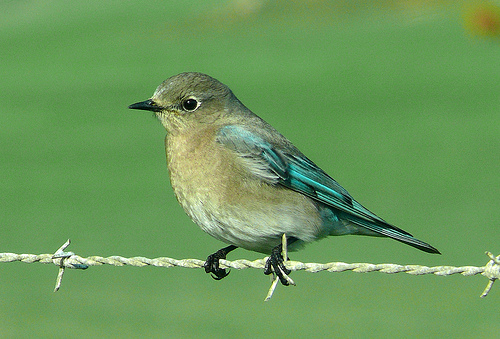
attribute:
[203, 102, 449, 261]
wings — green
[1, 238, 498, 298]
wire — white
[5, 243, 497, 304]
wire — barbed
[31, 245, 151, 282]
wires — barbed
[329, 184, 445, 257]
tail — blue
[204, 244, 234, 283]
leg — black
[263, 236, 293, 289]
leg — black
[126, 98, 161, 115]
beak — pointy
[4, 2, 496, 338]
grass — blurry, green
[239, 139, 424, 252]
wing — blue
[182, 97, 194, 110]
eye — black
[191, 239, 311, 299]
feet — black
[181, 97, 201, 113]
eye — open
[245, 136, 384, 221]
feather — blue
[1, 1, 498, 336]
background — green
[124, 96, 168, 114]
beak — black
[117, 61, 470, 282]
bird — sitting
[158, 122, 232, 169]
neck — brown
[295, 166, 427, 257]
tail — blue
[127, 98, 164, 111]
beak — black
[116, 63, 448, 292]
bird — perched, small, little